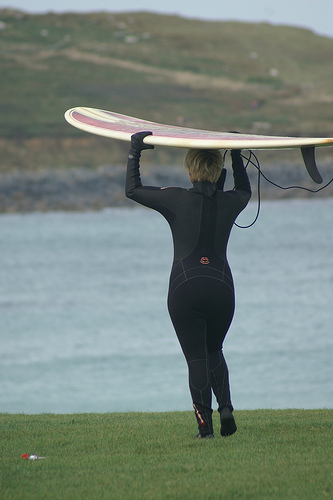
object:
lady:
[125, 131, 252, 440]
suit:
[124, 156, 250, 420]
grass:
[2, 407, 332, 498]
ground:
[114, 408, 202, 476]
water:
[92, 261, 155, 291]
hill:
[225, 18, 315, 80]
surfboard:
[63, 99, 333, 185]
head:
[183, 149, 224, 185]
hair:
[184, 141, 224, 183]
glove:
[128, 131, 155, 158]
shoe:
[219, 406, 237, 437]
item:
[200, 256, 209, 264]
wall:
[20, 144, 97, 210]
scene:
[0, 5, 333, 500]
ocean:
[0, 197, 333, 415]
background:
[0, 0, 333, 216]